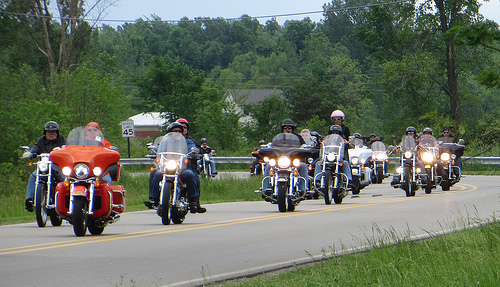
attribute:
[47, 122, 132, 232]
motorcycle — orange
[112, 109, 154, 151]
sign — speed limit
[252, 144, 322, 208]
motorcycle — black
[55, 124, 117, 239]
motorcycle — red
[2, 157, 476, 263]
lines — yellow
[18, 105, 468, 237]
motorcyles road — group 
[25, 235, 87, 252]
lines — yellow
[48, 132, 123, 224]
motorcycle — orange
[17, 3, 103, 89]
tree — tall, leafy, green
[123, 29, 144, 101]
tree — green, tall, leafy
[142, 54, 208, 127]
tree — green, tall, leafy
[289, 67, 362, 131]
tree — green, tall, leafy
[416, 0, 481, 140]
tree — green, tall, leafy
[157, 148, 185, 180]
headlights — on